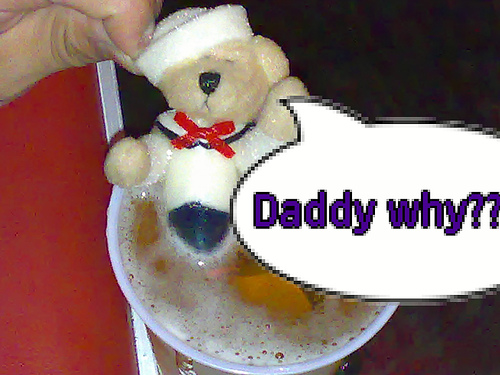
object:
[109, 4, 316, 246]
bear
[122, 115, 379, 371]
cup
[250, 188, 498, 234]
quotation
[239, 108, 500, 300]
outline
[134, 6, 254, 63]
cap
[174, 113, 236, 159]
ribbon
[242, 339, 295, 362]
bubble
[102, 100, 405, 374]
drink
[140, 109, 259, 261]
sailor uniform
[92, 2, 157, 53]
fingers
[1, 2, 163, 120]
person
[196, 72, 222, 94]
nose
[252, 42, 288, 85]
ear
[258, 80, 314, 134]
hand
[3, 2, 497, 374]
picture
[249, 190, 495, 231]
letter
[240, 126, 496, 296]
bubble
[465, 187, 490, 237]
question mark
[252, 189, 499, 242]
text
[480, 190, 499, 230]
question mark